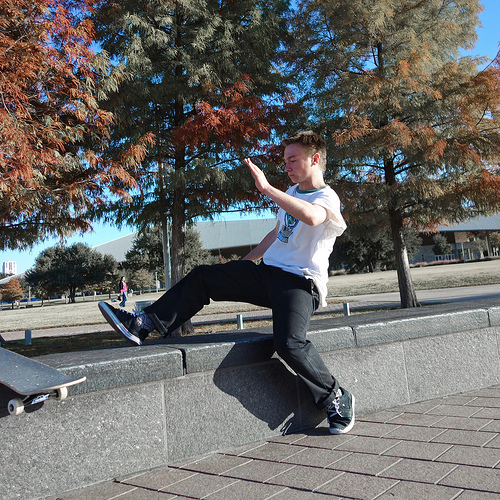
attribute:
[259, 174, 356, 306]
t shirt — white 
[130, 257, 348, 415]
pant — black 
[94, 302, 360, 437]
shoe — black 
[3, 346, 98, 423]
skating — black 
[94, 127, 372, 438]
man — Young, black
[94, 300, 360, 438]
shoes — black tennis 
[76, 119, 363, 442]
man — Young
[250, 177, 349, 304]
t-shirt — white 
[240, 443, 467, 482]
pavers — Gray brown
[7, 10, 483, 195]
trees — Pine , background.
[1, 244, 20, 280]
building — Top part , background.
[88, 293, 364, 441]
sneakers — white athletic , black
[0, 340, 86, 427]
skateboarding — man 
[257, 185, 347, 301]
shirt — white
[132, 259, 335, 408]
jeans — black